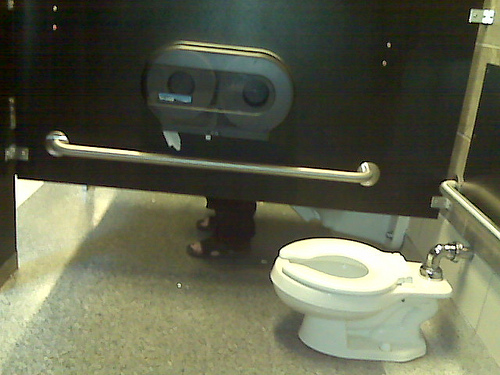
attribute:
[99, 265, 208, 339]
floor — gray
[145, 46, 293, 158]
dispenser — black, hanging, big, close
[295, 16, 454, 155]
wall — black, dark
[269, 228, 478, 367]
toilet — small, white, clean, sitting, close, metal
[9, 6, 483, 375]
restroom — clean, black, big, full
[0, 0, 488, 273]
wall — black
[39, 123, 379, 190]
rod — metallic